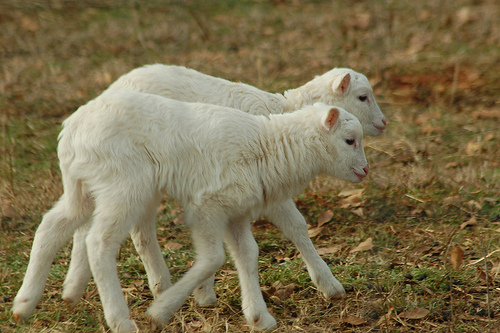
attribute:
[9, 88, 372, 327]
sheep — standing, white, behind, one, small, walking, bright, light, furry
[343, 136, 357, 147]
eye — dark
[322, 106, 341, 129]
ear — pointy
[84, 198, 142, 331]
leg — long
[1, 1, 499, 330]
grass — dry, field, green